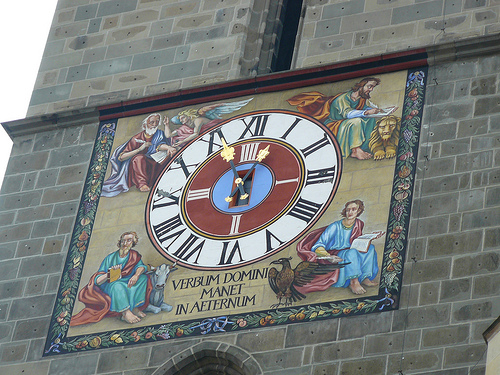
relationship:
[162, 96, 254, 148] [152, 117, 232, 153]
angel of angel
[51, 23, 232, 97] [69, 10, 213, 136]
bricks on building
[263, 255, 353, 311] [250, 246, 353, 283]
bird of bird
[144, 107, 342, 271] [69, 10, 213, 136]
clock on building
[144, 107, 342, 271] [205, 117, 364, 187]
clock has numerals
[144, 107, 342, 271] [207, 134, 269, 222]
clock has minute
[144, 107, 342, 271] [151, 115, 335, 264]
clock with roman numerals